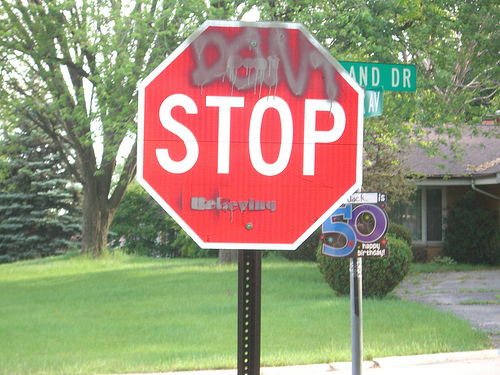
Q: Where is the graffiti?
A: Stop sign.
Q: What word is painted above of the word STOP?
A: Dont.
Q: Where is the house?
A: Middle right side of the image.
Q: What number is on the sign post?
A: 50.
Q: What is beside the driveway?
A: Shrubs.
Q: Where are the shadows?
A: Grass.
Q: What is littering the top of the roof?
A: Leaves.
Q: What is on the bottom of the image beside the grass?
A: Sidewalk.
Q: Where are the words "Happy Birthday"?
A: Below the number 50.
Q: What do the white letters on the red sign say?
A: Stop.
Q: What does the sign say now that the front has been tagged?
A: Don't stop believing.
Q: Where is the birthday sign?
A: On the street sign post.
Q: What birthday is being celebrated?
A: 50th.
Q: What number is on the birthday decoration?
A: 50.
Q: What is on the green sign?
A: Street names.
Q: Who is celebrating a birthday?
A: Jack.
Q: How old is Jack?
A: 50.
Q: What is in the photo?
A: A stop sign.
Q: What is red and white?
A: The sign.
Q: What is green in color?
A: The grass.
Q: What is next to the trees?
A: A house.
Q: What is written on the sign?
A: Don't.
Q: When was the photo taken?
A: During the daytime.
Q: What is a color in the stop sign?
A: Red.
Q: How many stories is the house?
A: One.